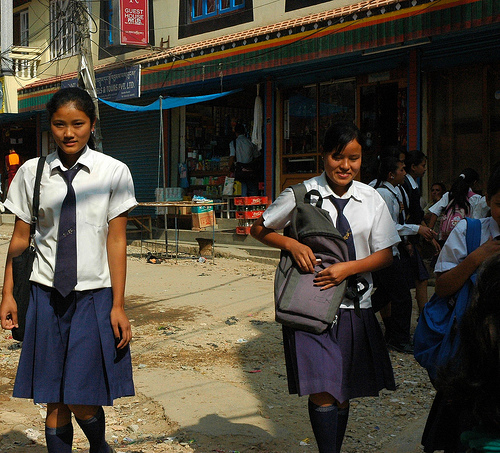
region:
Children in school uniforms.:
[56, 105, 414, 402]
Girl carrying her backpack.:
[270, 188, 352, 345]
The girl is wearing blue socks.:
[297, 394, 360, 439]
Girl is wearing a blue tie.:
[39, 152, 93, 314]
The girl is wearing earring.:
[86, 127, 99, 136]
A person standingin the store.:
[203, 108, 262, 210]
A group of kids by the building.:
[379, 138, 467, 277]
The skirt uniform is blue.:
[17, 291, 143, 391]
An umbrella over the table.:
[106, 76, 225, 230]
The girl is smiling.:
[305, 135, 385, 193]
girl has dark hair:
[44, 90, 94, 135]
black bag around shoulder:
[5, 134, 89, 331]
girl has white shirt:
[11, 165, 145, 297]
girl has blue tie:
[32, 144, 106, 305]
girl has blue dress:
[12, 301, 156, 403]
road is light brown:
[138, 250, 219, 334]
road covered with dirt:
[150, 280, 272, 431]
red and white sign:
[105, 0, 147, 57]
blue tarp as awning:
[84, 71, 225, 131]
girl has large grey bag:
[288, 167, 348, 329]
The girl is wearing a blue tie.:
[51, 167, 96, 294]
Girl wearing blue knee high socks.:
[288, 385, 340, 440]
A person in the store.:
[211, 120, 266, 189]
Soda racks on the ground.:
[225, 188, 274, 235]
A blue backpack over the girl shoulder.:
[273, 177, 344, 345]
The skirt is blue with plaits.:
[15, 287, 135, 392]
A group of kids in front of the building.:
[371, 135, 476, 242]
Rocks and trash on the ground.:
[361, 320, 443, 435]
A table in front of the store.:
[113, 185, 213, 262]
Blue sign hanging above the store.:
[59, 59, 144, 104]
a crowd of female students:
[12, 73, 487, 438]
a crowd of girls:
[21, 89, 496, 412]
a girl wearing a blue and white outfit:
[261, 121, 397, 446]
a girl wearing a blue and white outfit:
[6, 89, 151, 451]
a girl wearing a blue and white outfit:
[421, 163, 498, 329]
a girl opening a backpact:
[252, 123, 384, 334]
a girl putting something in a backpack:
[253, 120, 398, 350]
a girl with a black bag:
[1, 77, 138, 351]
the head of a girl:
[38, 86, 101, 169]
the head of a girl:
[320, 121, 365, 196]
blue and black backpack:
[278, 182, 348, 332]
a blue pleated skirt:
[13, 280, 135, 403]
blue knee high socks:
[305, 398, 349, 450]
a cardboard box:
[192, 209, 215, 226]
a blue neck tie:
[52, 160, 81, 297]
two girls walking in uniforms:
[6, 83, 397, 450]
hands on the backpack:
[286, 241, 347, 286]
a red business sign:
[117, 0, 147, 45]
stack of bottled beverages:
[235, 202, 265, 234]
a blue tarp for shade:
[97, 93, 243, 113]